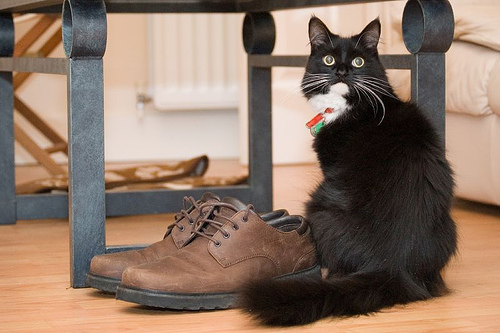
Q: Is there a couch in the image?
A: Yes, there is a couch.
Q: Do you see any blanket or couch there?
A: Yes, there is a couch.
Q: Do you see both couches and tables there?
A: Yes, there are both a couch and a table.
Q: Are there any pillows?
A: No, there are no pillows.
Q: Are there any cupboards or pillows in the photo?
A: No, there are no pillows or cupboards.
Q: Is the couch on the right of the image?
A: Yes, the couch is on the right of the image.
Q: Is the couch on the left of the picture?
A: No, the couch is on the right of the image.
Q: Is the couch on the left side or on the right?
A: The couch is on the right of the image.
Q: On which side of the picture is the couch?
A: The couch is on the right of the image.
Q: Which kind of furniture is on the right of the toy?
A: The piece of furniture is a couch.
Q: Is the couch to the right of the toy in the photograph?
A: Yes, the couch is to the right of the toy.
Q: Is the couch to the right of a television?
A: No, the couch is to the right of the toy.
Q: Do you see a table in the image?
A: Yes, there is a table.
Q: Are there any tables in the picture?
A: Yes, there is a table.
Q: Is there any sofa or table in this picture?
A: Yes, there is a table.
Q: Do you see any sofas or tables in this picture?
A: Yes, there is a table.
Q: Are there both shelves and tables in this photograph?
A: No, there is a table but no shelves.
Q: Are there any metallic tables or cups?
A: Yes, there is a metal table.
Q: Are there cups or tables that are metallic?
A: Yes, the table is metallic.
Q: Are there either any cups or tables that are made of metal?
A: Yes, the table is made of metal.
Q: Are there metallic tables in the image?
A: Yes, there is a metal table.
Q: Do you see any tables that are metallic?
A: Yes, there is a table that is metallic.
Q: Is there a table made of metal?
A: Yes, there is a table that is made of metal.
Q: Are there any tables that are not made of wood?
A: Yes, there is a table that is made of metal.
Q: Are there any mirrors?
A: No, there are no mirrors.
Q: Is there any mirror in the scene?
A: No, there are no mirrors.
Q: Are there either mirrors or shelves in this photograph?
A: No, there are no mirrors or shelves.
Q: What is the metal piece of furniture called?
A: The piece of furniture is a table.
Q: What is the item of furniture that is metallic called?
A: The piece of furniture is a table.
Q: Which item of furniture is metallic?
A: The piece of furniture is a table.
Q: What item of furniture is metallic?
A: The piece of furniture is a table.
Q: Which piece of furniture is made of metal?
A: The piece of furniture is a table.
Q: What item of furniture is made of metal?
A: The piece of furniture is a table.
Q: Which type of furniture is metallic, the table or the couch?
A: The table is metallic.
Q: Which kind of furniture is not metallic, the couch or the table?
A: The couch is not metallic.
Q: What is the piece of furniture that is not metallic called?
A: The piece of furniture is a couch.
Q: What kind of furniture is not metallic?
A: The furniture is a couch.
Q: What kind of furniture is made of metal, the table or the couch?
A: The table is made of metal.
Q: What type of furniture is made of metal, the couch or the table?
A: The table is made of metal.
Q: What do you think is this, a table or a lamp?
A: This is a table.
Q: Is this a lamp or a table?
A: This is a table.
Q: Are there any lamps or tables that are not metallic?
A: No, there is a table but it is metallic.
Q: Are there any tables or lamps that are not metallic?
A: No, there is a table but it is metallic.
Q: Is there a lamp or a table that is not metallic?
A: No, there is a table but it is metallic.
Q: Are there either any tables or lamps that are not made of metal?
A: No, there is a table but it is made of metal.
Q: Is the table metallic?
A: Yes, the table is metallic.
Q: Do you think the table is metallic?
A: Yes, the table is metallic.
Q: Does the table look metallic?
A: Yes, the table is metallic.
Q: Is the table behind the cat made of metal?
A: Yes, the table is made of metal.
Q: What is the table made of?
A: The table is made of metal.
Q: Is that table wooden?
A: No, the table is metallic.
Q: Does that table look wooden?
A: No, the table is metallic.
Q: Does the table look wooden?
A: No, the table is metallic.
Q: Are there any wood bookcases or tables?
A: No, there is a table but it is metallic.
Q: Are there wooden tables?
A: No, there is a table but it is metallic.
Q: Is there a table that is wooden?
A: No, there is a table but it is metallic.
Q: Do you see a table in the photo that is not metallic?
A: No, there is a table but it is metallic.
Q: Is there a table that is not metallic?
A: No, there is a table but it is metallic.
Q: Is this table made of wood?
A: No, the table is made of metal.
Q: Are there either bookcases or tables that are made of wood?
A: No, there is a table but it is made of metal.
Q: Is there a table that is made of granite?
A: No, there is a table but it is made of metal.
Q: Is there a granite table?
A: No, there is a table but it is made of metal.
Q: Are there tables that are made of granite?
A: No, there is a table but it is made of metal.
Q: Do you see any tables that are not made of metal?
A: No, there is a table but it is made of metal.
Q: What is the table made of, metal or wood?
A: The table is made of metal.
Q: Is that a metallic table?
A: Yes, that is a metallic table.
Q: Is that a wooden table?
A: No, that is a metallic table.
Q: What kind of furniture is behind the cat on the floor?
A: The piece of furniture is a table.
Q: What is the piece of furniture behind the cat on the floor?
A: The piece of furniture is a table.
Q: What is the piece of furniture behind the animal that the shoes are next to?
A: The piece of furniture is a table.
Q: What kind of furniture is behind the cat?
A: The piece of furniture is a table.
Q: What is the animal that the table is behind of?
A: The animal is a cat.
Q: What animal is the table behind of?
A: The table is behind the cat.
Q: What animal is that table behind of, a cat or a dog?
A: The table is behind a cat.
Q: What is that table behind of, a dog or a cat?
A: The table is behind a cat.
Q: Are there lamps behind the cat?
A: No, there is a table behind the cat.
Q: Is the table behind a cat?
A: Yes, the table is behind a cat.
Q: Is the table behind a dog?
A: No, the table is behind a cat.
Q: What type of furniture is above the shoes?
A: The piece of furniture is a table.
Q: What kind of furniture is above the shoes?
A: The piece of furniture is a table.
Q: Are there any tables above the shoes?
A: Yes, there is a table above the shoes.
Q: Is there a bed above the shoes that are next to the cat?
A: No, there is a table above the shoes.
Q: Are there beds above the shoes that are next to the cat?
A: No, there is a table above the shoes.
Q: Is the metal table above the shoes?
A: Yes, the table is above the shoes.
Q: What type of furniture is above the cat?
A: The piece of furniture is a table.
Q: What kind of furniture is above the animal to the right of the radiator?
A: The piece of furniture is a table.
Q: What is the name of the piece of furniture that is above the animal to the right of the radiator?
A: The piece of furniture is a table.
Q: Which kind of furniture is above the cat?
A: The piece of furniture is a table.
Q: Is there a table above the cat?
A: Yes, there is a table above the cat.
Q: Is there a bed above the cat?
A: No, there is a table above the cat.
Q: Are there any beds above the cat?
A: No, there is a table above the cat.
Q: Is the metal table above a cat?
A: Yes, the table is above a cat.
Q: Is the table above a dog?
A: No, the table is above a cat.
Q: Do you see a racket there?
A: No, there are no rackets.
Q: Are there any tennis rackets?
A: No, there are no tennis rackets.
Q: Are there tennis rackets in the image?
A: No, there are no tennis rackets.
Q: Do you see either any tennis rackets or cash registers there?
A: No, there are no tennis rackets or cash registers.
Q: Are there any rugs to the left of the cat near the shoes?
A: Yes, there is a rug to the left of the cat.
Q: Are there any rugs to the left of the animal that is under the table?
A: Yes, there is a rug to the left of the cat.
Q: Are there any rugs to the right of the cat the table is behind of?
A: No, the rug is to the left of the cat.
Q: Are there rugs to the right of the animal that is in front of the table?
A: No, the rug is to the left of the cat.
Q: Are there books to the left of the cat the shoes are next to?
A: No, there is a rug to the left of the cat.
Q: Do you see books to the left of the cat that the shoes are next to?
A: No, there is a rug to the left of the cat.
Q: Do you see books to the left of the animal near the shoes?
A: No, there is a rug to the left of the cat.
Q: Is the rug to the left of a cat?
A: Yes, the rug is to the left of a cat.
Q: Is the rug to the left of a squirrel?
A: No, the rug is to the left of a cat.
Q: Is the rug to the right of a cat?
A: No, the rug is to the left of a cat.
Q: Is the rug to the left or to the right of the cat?
A: The rug is to the left of the cat.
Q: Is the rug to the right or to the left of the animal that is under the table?
A: The rug is to the left of the cat.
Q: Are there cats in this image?
A: Yes, there is a cat.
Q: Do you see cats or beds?
A: Yes, there is a cat.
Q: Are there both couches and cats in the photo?
A: Yes, there are both a cat and a couch.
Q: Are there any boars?
A: No, there are no boars.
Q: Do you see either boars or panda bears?
A: No, there are no boars or panda bears.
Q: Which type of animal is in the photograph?
A: The animal is a cat.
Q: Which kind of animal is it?
A: The animal is a cat.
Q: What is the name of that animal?
A: That is a cat.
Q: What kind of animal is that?
A: That is a cat.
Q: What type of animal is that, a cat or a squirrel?
A: That is a cat.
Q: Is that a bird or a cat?
A: That is a cat.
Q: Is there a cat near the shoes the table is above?
A: Yes, there is a cat near the shoes.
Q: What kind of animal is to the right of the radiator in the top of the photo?
A: The animal is a cat.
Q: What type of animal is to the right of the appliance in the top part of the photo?
A: The animal is a cat.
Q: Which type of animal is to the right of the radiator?
A: The animal is a cat.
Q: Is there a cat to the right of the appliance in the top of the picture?
A: Yes, there is a cat to the right of the radiator.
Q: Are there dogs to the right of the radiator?
A: No, there is a cat to the right of the radiator.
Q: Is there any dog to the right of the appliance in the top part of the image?
A: No, there is a cat to the right of the radiator.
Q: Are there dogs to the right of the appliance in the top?
A: No, there is a cat to the right of the radiator.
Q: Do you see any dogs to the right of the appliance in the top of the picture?
A: No, there is a cat to the right of the radiator.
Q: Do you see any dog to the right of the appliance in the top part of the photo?
A: No, there is a cat to the right of the radiator.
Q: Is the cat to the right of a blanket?
A: No, the cat is to the right of the radiator.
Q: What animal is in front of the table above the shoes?
A: The cat is in front of the table.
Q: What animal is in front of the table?
A: The cat is in front of the table.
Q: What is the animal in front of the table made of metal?
A: The animal is a cat.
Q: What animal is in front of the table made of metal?
A: The animal is a cat.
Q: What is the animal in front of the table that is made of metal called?
A: The animal is a cat.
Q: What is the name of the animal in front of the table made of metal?
A: The animal is a cat.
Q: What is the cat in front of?
A: The cat is in front of the table.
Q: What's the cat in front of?
A: The cat is in front of the table.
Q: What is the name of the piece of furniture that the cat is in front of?
A: The piece of furniture is a table.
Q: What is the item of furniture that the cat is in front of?
A: The piece of furniture is a table.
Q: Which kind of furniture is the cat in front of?
A: The cat is in front of the table.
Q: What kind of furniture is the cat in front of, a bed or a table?
A: The cat is in front of a table.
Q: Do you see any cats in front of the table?
A: Yes, there is a cat in front of the table.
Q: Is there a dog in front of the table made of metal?
A: No, there is a cat in front of the table.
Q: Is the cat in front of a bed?
A: No, the cat is in front of a table.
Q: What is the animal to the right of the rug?
A: The animal is a cat.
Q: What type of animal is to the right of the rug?
A: The animal is a cat.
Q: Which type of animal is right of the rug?
A: The animal is a cat.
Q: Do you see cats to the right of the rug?
A: Yes, there is a cat to the right of the rug.